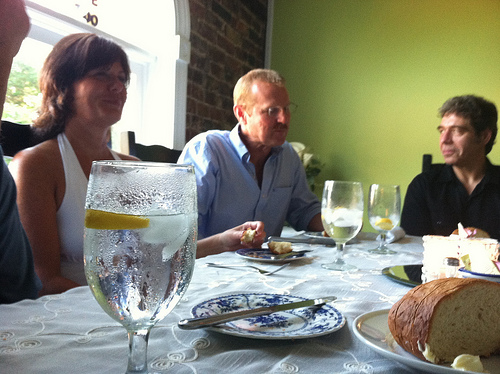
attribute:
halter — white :
[40, 132, 110, 283]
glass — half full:
[314, 174, 369, 279]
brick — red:
[177, 1, 271, 75]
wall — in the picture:
[184, 1, 267, 143]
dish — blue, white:
[193, 288, 348, 345]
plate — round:
[125, 281, 322, 371]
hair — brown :
[231, 67, 283, 103]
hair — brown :
[29, 25, 133, 133]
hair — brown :
[436, 93, 496, 135]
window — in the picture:
[14, 1, 209, 179]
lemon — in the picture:
[84, 205, 148, 230]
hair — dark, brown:
[32, 34, 133, 133]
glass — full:
[81, 160, 195, 371]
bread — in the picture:
[363, 251, 473, 356]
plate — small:
[189, 286, 349, 348]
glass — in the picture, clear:
[85, 156, 202, 368]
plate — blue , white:
[195, 283, 353, 348]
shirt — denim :
[177, 121, 321, 240]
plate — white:
[352, 306, 499, 371]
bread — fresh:
[389, 276, 499, 372]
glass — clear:
[309, 167, 366, 284]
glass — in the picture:
[363, 180, 405, 255]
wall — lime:
[355, 46, 390, 133]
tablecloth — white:
[1, 212, 423, 370]